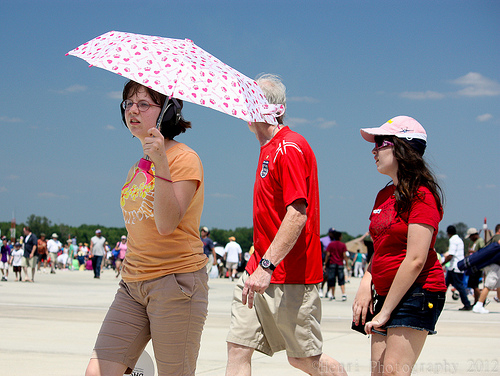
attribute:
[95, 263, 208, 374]
short pant — khaki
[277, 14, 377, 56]
sky — clear, blue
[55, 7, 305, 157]
umbrella — white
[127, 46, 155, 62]
hearts — pink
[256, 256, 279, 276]
watch — black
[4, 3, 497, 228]
sky — blue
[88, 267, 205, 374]
shorts — light, brown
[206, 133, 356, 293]
shirt — red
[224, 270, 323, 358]
shorts — tan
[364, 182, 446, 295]
shirt — red